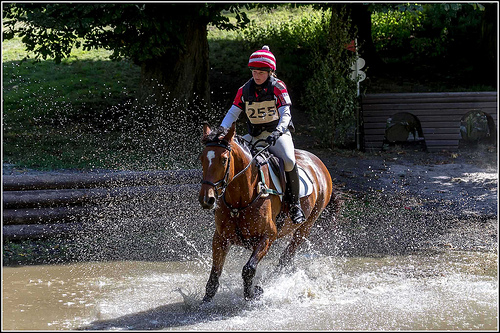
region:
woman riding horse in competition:
[161, 41, 353, 311]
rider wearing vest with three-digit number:
[192, 36, 342, 222]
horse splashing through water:
[110, 115, 400, 305]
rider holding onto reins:
[162, 116, 312, 221]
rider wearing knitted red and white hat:
[245, 35, 285, 80]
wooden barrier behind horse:
[15, 155, 350, 280]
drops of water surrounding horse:
[80, 90, 395, 260]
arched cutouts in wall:
[335, 82, 495, 167]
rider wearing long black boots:
[185, 110, 341, 240]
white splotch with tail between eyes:
[185, 116, 230, 187]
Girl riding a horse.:
[181, 18, 319, 311]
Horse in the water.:
[87, 107, 271, 318]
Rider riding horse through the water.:
[95, 105, 270, 275]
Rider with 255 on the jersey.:
[230, 75, 335, 140]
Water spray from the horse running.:
[92, 55, 299, 320]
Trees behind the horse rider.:
[131, 22, 353, 90]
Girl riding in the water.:
[151, 27, 372, 284]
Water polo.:
[67, 70, 338, 317]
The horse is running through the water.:
[48, 27, 474, 277]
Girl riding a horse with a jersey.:
[182, 11, 367, 256]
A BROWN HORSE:
[170, 122, 337, 308]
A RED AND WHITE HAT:
[235, 38, 280, 75]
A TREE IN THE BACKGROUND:
[21, 8, 231, 108]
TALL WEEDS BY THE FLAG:
[298, 37, 374, 156]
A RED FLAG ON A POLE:
[340, 35, 373, 162]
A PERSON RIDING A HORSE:
[195, 39, 348, 314]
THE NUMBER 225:
[223, 90, 303, 131]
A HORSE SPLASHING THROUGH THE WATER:
[144, 116, 365, 318]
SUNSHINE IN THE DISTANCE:
[204, 6, 343, 43]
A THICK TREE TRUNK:
[161, 22, 218, 108]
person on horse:
[163, 32, 353, 286]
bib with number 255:
[232, 97, 291, 129]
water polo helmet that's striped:
[229, 36, 284, 85]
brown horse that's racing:
[176, 127, 344, 313]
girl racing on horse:
[177, 44, 335, 306]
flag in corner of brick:
[330, 24, 397, 171]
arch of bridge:
[359, 70, 450, 175]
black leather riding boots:
[273, 155, 312, 235]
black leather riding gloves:
[213, 121, 290, 146]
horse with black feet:
[198, 252, 270, 319]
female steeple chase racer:
[181, 39, 343, 309]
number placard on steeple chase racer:
[241, 94, 280, 125]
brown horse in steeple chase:
[183, 120, 337, 306]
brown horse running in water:
[181, 117, 382, 331]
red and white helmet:
[242, 40, 279, 72]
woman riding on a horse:
[236, 42, 301, 178]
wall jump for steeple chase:
[351, 86, 499, 151]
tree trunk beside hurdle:
[143, 5, 218, 115]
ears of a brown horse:
[198, 116, 240, 154]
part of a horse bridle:
[191, 167, 235, 194]